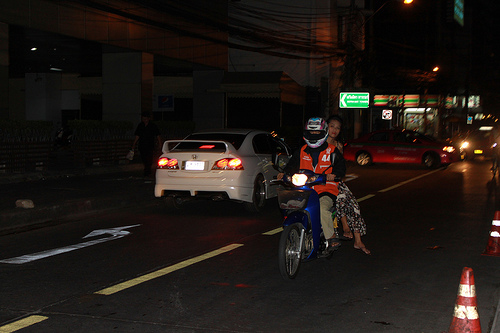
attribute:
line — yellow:
[260, 224, 283, 235]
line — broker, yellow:
[88, 237, 273, 289]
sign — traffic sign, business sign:
[339, 91, 371, 108]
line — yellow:
[378, 167, 448, 194]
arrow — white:
[13, 201, 164, 282]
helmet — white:
[299, 113, 329, 145]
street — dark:
[0, 152, 496, 331]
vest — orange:
[289, 144, 341, 189]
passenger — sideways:
[289, 109, 342, 255]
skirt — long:
[334, 180, 370, 237]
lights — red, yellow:
[221, 159, 238, 171]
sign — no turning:
[377, 105, 392, 121]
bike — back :
[267, 161, 337, 282]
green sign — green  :
[333, 88, 375, 113]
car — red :
[343, 127, 465, 168]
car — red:
[344, 120, 455, 170]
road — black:
[35, 166, 196, 316]